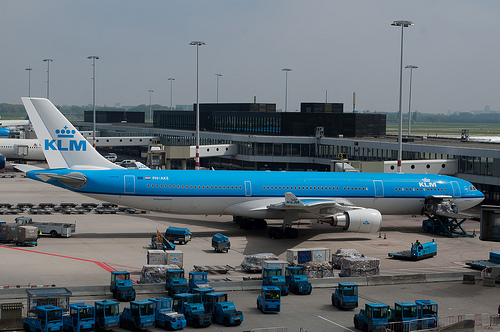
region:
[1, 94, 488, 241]
planes pulled up to terminal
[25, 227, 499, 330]
several blue carts to service planes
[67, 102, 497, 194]
several glass windows on building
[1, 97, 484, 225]
planes are blue and white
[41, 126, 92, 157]
plane says KLM in blue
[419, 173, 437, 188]
plane says KLM in white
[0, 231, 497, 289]
red paint in stripes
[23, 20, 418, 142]
several tall light posts surround building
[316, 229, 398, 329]
white paint on concrete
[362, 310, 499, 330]
white and red fence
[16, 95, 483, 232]
blue and white airplane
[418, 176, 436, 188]
airline name in white text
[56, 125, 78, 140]
blue crown on the tail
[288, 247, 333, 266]
a white luggage cart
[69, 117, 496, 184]
a large airport terminal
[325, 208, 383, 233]
engine on the plane's wing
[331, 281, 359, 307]
blue cart vehicle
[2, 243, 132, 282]
red painted lines on the ground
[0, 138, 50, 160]
airplane in the background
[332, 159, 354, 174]
passenger boarding hallway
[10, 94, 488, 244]
a blue and white airplane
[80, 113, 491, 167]
the terminal of an airport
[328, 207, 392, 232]
the engine on a plane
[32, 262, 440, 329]
the transport cars at an airport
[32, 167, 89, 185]
the tail wing of a plane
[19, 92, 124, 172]
the tail of a plane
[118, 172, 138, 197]
a door of a plane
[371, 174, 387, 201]
a door of a plane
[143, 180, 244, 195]
the windows of a plane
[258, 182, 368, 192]
the windows of a plane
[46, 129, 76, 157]
logo on the plane.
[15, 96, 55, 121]
tail of the plane.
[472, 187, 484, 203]
nose of the plane.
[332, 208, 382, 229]
engine of the plane.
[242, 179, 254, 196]
door on the plane.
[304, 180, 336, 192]
windows on the plane.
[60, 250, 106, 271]
red paint on tarmac.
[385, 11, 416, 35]
lights on a pole.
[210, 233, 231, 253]
cart near the plane.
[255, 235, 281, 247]
shadow on the tarmac.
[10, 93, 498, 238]
Large blue colored airliner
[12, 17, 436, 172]
Group of tall masts with flood lights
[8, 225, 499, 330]
Group of blue utility trucks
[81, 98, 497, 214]
Line of low height buildings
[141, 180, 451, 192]
Line of small windows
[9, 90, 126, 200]
Aircraft ail end with branding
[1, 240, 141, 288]
Red painted markings on the tarmac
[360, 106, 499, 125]
Vegetation in the distance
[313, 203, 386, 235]
Large white jet engine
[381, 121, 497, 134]
Section of open field background